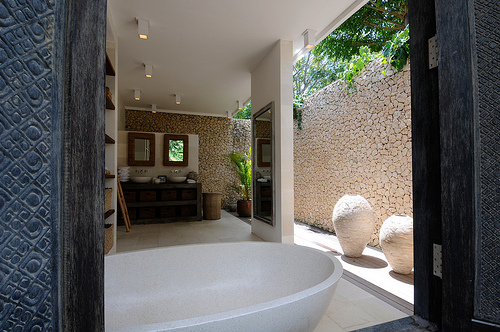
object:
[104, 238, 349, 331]
rim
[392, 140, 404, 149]
stone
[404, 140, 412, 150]
stone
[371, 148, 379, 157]
stone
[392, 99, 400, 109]
stone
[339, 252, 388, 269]
shadow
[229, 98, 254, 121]
plant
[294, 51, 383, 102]
edge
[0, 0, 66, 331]
pattern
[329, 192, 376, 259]
pot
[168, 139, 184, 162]
flower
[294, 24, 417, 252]
wall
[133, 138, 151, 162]
mirror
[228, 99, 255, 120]
hedge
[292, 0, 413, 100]
tree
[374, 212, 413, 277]
statues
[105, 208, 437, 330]
ground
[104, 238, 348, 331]
bathtub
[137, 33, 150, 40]
lights